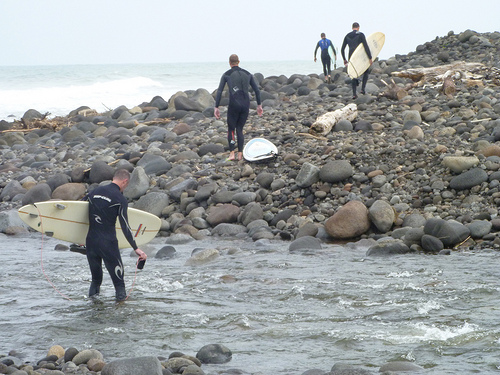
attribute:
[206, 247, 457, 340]
water — splashing, flowing, part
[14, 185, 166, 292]
board — surf, whtie, part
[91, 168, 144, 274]
man — ligh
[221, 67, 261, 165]
man — walking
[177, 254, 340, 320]
waves — foamy, white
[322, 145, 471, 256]
rocks — large, small, bunch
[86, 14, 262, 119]
sky — clear, blue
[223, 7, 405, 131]
people — four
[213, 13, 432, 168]
surfers — four